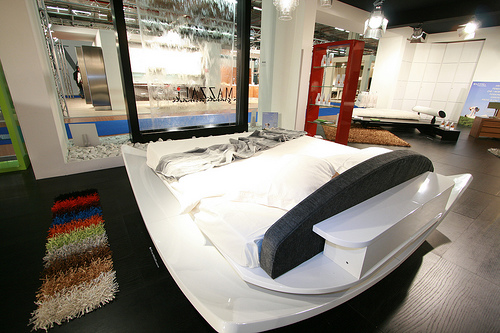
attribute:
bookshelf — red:
[303, 36, 364, 149]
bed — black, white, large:
[118, 129, 473, 332]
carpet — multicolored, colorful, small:
[29, 185, 119, 332]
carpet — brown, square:
[322, 118, 414, 149]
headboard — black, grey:
[247, 151, 436, 281]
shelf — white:
[312, 170, 455, 278]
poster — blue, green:
[457, 80, 499, 129]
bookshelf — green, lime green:
[0, 61, 33, 173]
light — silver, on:
[359, 0, 391, 42]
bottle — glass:
[319, 53, 326, 67]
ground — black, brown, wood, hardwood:
[0, 122, 498, 332]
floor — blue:
[0, 97, 358, 143]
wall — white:
[372, 23, 499, 136]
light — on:
[267, 0, 303, 21]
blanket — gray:
[145, 121, 306, 179]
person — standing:
[69, 63, 84, 102]